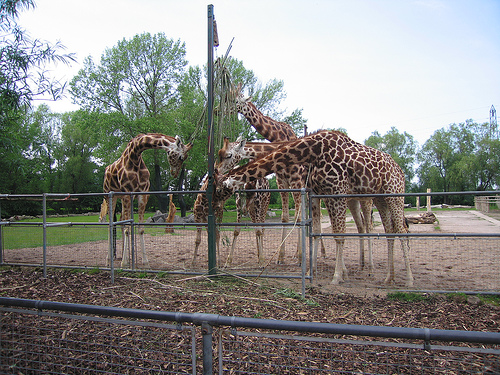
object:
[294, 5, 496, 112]
sky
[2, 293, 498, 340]
metal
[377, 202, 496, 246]
ground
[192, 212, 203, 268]
leg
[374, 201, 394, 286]
legs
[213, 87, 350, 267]
giraffe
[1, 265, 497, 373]
ground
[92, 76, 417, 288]
herd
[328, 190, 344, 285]
leg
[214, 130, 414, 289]
giraffe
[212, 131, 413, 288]
giraffes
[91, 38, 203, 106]
leaves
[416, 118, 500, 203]
trees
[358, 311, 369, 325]
part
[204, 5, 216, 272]
pole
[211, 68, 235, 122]
food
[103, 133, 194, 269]
giraffe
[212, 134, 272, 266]
giraffe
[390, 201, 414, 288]
leg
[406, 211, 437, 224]
stump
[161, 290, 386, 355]
mulch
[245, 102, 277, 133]
neck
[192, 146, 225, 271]
giraffe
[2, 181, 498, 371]
enclosure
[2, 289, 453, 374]
dirt